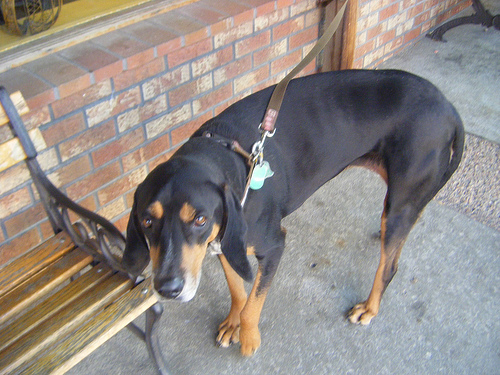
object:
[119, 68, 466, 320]
dog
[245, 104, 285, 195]
leash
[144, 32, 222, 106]
wall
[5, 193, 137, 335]
bench